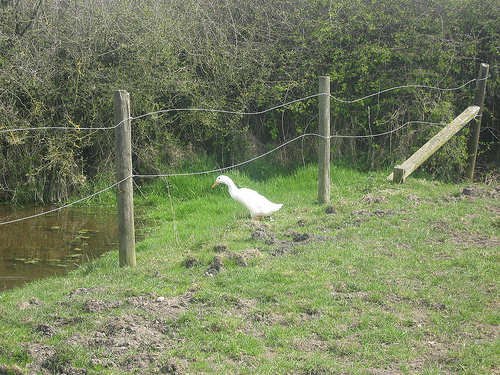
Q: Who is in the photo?
A: Nobody.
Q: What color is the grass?
A: Green.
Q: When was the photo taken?
A: Daytime.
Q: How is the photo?
A: Clear.